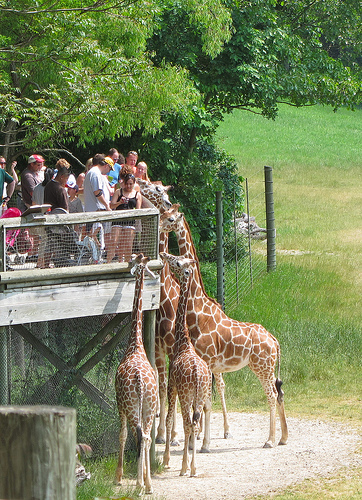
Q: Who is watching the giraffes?
A: A group of people.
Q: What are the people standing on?
A: A raised platform.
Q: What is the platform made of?
A: Wood.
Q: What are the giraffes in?
A: An enclosure.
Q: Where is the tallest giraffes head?
A: Above the fence by the people.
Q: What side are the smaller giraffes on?
A: The left side.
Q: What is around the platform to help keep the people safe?
A: A fence.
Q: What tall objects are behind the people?
A: Trees.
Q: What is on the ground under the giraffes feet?
A: Gravel.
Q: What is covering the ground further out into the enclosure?
A: Grass.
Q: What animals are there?
A: Giraffes.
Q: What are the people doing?
A: Looking.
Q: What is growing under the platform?
A: Weeds.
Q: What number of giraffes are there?
A: Four.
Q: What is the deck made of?
A: Wood.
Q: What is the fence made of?
A: Metal.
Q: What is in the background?
A: Trees.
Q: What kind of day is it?
A: Sunny.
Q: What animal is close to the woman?
A: Giraffe.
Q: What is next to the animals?
A: Fence.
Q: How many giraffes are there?
A: Four.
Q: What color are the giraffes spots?
A: Brown.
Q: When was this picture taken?
A: Daytime.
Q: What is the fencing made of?
A: Wood and wire.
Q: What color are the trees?
A: Green.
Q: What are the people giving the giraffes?
A: Food.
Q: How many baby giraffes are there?
A: Two.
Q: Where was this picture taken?
A: Zoo.